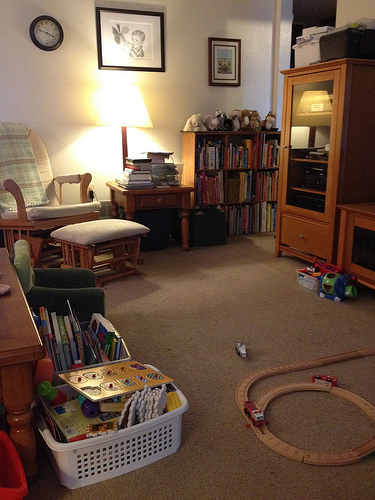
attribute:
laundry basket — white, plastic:
[31, 363, 190, 492]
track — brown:
[234, 343, 373, 468]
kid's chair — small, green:
[13, 240, 105, 322]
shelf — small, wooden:
[179, 131, 282, 242]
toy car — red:
[312, 259, 343, 279]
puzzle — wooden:
[59, 360, 175, 403]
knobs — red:
[78, 363, 158, 388]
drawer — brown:
[141, 194, 178, 209]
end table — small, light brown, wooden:
[106, 179, 195, 253]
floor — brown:
[22, 231, 375, 500]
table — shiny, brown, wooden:
[1, 248, 46, 483]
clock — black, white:
[30, 15, 65, 53]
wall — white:
[1, 0, 276, 206]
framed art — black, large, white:
[96, 8, 167, 74]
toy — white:
[235, 341, 249, 359]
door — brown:
[280, 69, 341, 227]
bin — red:
[2, 430, 27, 500]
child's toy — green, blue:
[316, 270, 356, 303]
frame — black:
[28, 16, 64, 52]